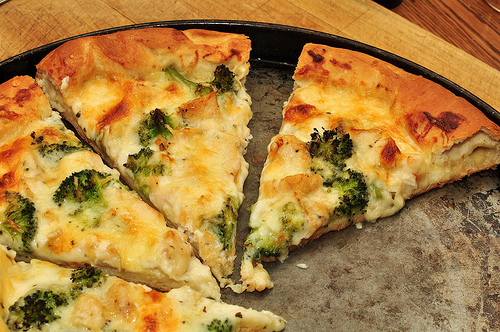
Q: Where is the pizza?
A: In a tray.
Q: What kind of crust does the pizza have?
A: Stuffed.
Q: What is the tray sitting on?
A: A wooden surface.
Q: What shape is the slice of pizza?
A: Triangle.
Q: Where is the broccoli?
A: On the pizza.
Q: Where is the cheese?
A: On the pizza.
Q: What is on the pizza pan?
A: Pizza.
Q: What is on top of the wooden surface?
A: A pizza pan.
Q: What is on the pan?
A: Pizza.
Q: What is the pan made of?
A: Metal.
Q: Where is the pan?
A: Table.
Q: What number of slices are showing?
A: 4.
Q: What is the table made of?
A: Wood.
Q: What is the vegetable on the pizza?
A: Broccoli.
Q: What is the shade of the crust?
A: Brown.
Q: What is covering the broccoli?
A: Cheese.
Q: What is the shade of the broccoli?
A: Green.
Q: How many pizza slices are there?
A: Four.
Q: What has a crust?
A: Pizza.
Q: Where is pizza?
A: On a pan.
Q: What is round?
A: A pan.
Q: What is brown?
A: Table.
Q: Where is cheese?
A: On pizza.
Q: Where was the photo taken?
A: Near pizza.